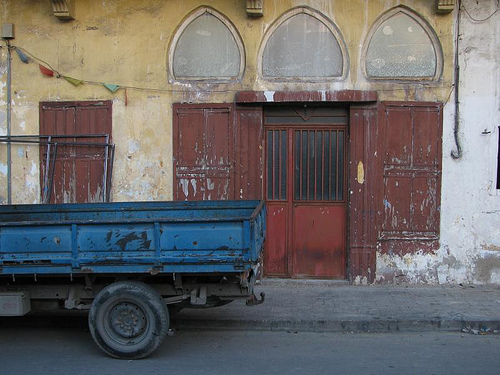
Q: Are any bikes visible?
A: No, there are no bikes.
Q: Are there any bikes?
A: No, there are no bikes.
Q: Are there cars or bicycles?
A: No, there are no bicycles or cars.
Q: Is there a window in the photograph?
A: Yes, there is a window.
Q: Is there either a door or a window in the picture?
A: Yes, there is a window.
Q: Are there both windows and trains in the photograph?
A: No, there is a window but no trains.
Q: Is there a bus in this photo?
A: No, there are no buses.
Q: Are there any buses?
A: No, there are no buses.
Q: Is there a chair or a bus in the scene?
A: No, there are no buses or chairs.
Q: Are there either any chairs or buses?
A: No, there are no buses or chairs.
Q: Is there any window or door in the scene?
A: Yes, there is a door.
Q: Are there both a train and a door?
A: No, there is a door but no trains.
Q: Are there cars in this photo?
A: No, there are no cars.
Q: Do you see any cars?
A: No, there are no cars.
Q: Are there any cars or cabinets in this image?
A: No, there are no cars or cabinets.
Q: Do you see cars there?
A: No, there are no cars.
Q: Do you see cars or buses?
A: No, there are no cars or buses.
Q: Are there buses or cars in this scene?
A: No, there are no cars or buses.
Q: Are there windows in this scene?
A: Yes, there is a window.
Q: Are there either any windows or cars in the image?
A: Yes, there is a window.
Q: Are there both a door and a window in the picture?
A: Yes, there are both a window and a door.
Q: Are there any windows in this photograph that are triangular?
A: Yes, there is a triangular window.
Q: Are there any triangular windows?
A: Yes, there is a triangular window.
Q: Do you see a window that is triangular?
A: Yes, there is a window that is triangular.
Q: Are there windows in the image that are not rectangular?
A: Yes, there is a triangular window.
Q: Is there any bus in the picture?
A: No, there are no buses.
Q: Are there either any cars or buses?
A: No, there are no buses or cars.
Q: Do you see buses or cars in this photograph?
A: No, there are no buses or cars.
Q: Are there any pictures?
A: No, there are no pictures.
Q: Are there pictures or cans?
A: No, there are no pictures or cans.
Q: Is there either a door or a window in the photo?
A: Yes, there is a door.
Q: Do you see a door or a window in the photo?
A: Yes, there is a door.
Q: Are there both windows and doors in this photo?
A: Yes, there are both a door and windows.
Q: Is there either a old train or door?
A: Yes, there is an old door.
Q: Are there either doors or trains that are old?
A: Yes, the door is old.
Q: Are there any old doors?
A: Yes, there is an old door.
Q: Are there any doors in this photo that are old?
A: Yes, there is a door that is old.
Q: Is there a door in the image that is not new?
A: Yes, there is a old door.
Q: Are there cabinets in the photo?
A: No, there are no cabinets.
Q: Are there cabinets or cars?
A: No, there are no cabinets or cars.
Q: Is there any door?
A: Yes, there is a door.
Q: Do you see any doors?
A: Yes, there is a door.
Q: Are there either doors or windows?
A: Yes, there is a door.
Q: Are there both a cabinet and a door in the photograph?
A: No, there is a door but no cabinets.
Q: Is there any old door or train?
A: Yes, there is an old door.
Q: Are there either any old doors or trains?
A: Yes, there is an old door.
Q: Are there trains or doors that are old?
A: Yes, the door is old.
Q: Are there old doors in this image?
A: Yes, there is an old door.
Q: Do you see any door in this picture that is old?
A: Yes, there is a door that is old.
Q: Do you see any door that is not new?
A: Yes, there is a old door.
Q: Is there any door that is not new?
A: Yes, there is a old door.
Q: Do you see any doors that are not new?
A: Yes, there is a old door.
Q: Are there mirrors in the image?
A: No, there are no mirrors.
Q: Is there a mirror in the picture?
A: No, there are no mirrors.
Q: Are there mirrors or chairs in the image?
A: No, there are no mirrors or chairs.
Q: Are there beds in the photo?
A: Yes, there is a bed.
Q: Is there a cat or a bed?
A: Yes, there is a bed.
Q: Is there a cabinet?
A: No, there are no cabinets.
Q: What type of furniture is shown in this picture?
A: The furniture is a bed.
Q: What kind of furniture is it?
A: The piece of furniture is a bed.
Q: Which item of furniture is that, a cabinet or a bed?
A: This is a bed.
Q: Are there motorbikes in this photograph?
A: No, there are no motorbikes.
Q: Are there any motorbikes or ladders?
A: No, there are no motorbikes or ladders.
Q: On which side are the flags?
A: The flags are on the left of the image.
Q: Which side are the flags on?
A: The flags are on the left of the image.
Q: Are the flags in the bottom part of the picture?
A: No, the flags are in the top of the image.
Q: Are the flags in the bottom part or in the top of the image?
A: The flags are in the top of the image.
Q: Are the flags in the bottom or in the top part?
A: The flags are in the top of the image.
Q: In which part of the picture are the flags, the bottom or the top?
A: The flags are in the top of the image.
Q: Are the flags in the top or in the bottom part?
A: The flags are in the top of the image.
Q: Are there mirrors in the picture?
A: No, there are no mirrors.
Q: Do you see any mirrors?
A: No, there are no mirrors.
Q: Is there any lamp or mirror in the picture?
A: No, there are no mirrors or lamps.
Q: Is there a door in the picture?
A: Yes, there is a door.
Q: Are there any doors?
A: Yes, there is a door.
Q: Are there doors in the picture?
A: Yes, there is a door.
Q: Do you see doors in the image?
A: Yes, there is a door.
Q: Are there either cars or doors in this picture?
A: Yes, there is a door.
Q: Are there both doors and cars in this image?
A: No, there is a door but no cars.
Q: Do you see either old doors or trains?
A: Yes, there is an old door.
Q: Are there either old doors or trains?
A: Yes, there is an old door.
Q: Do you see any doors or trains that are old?
A: Yes, the door is old.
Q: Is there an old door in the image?
A: Yes, there is an old door.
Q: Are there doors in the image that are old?
A: Yes, there is a door that is old.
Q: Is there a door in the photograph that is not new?
A: Yes, there is a old door.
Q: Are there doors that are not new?
A: Yes, there is a old door.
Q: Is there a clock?
A: No, there are no clocks.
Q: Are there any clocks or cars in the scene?
A: No, there are no clocks or cars.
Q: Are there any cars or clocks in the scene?
A: No, there are no clocks or cars.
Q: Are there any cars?
A: No, there are no cars.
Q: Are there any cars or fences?
A: No, there are no cars or fences.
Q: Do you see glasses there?
A: No, there are no glasses.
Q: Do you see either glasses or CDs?
A: No, there are no glasses or cds.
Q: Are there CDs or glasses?
A: No, there are no glasses or cds.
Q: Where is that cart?
A: The cart is on the road.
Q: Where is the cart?
A: The cart is on the road.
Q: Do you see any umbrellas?
A: No, there are no umbrellas.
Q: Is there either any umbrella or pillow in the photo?
A: No, there are no umbrellas or pillows.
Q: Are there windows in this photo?
A: Yes, there is a window.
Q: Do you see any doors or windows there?
A: Yes, there is a window.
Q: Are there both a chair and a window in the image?
A: No, there is a window but no chairs.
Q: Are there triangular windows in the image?
A: Yes, there is a triangular window.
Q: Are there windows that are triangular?
A: Yes, there is a window that is triangular.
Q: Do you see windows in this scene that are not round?
A: Yes, there is a triangular window.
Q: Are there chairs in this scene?
A: No, there are no chairs.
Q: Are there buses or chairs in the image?
A: No, there are no chairs or buses.